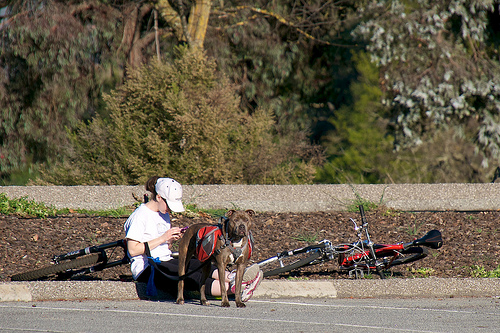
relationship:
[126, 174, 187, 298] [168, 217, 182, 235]
woman on ground phone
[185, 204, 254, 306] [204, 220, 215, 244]
brown dog with backpack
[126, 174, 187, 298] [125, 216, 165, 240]
woman a white shirt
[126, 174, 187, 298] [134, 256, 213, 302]
woman black black pants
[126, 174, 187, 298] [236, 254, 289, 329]
woman pink and white tennis shoes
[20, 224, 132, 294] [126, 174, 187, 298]
black bike to left of woman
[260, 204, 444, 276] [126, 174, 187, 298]
bike to right of woman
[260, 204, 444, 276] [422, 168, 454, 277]
bike has black seat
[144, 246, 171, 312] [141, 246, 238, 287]
blue ribbon tied to dog leash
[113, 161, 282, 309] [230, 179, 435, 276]
woman and dog near bike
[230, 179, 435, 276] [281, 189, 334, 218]
bike lying on ground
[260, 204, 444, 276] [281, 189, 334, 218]
bike on ground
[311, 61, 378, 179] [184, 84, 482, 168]
green foliage and trees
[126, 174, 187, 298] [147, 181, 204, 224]
woman in white hat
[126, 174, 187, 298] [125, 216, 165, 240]
woman in white shirt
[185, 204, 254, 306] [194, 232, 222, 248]
brown dog in red vest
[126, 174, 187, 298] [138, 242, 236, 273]
woman holding black leash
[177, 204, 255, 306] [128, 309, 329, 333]
brown dog in lot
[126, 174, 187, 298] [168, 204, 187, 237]
woman and staring at phone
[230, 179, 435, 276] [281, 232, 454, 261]
bike laying down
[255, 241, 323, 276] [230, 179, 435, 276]
black of bike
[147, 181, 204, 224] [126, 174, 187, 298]
white hat on woman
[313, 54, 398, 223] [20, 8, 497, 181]
green folliage in background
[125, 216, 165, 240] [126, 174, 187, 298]
white shirt on a woman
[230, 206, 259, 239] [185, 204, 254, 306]
head of brown dog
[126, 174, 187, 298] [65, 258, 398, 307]
woman on curb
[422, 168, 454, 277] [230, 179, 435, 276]
black seat on bike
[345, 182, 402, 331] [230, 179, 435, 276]
handle of bike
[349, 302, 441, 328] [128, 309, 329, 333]
concrete parking lot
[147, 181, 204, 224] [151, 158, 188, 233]
white hat on head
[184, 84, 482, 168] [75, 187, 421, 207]
trees behind wall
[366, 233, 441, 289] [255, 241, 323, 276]
black bike black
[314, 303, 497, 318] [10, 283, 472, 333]
white lines on parking lot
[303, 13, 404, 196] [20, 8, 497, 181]
leafy green tree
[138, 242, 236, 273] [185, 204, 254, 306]
black leash on dog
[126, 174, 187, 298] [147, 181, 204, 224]
woman with white hat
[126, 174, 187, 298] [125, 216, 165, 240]
woman has white shirt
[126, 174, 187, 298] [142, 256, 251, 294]
woman has black pants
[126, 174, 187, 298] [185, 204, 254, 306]
woman near brown dog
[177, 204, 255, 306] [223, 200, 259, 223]
brown dog jhas brown ears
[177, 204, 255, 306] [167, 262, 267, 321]
brown dog has brown legs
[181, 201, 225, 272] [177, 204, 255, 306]
red and grey case on brown dog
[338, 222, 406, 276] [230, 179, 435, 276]
red frame on bike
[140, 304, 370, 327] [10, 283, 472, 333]
white stripes on parking lot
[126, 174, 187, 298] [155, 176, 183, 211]
woman wearing white hat